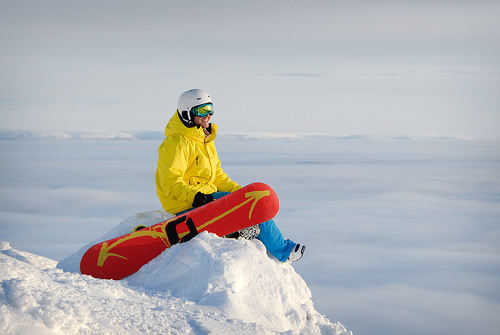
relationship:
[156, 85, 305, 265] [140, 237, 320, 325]
person sitting in snow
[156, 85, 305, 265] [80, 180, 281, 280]
person holding snowboard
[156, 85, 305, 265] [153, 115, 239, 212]
person wearing jacket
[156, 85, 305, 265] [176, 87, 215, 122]
person wearing helmet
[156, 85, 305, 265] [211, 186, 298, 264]
person wearing pants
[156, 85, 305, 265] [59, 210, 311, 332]
person sitting on snow mound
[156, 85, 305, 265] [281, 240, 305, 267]
person wearing shoe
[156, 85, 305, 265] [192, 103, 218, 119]
person wearing goggles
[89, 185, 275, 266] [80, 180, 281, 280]
design on snowboard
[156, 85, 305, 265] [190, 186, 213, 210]
person wearing glove